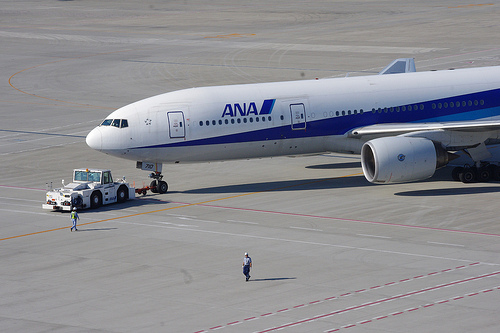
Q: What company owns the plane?
A: Ana.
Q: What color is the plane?
A: White and blue.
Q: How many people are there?
A: Two.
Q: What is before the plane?
A: Truck.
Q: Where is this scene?
A: Airport.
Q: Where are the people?
A: On the tarmac.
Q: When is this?
A: Daytime.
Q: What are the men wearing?
A: Hats.